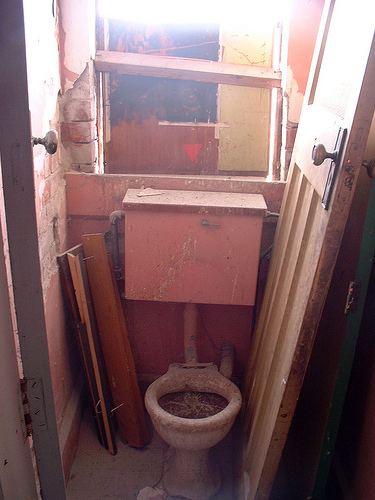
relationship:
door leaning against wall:
[214, 10, 345, 478] [274, 37, 363, 497]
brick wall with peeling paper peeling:
[24, 9, 81, 498] [24, 11, 171, 138]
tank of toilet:
[125, 189, 259, 302] [146, 366, 234, 497]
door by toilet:
[231, 0, 374, 477] [144, 361, 241, 498]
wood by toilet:
[52, 227, 152, 455] [146, 366, 234, 497]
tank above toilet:
[97, 190, 286, 305] [127, 339, 267, 475]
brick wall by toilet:
[24, 9, 81, 498] [144, 361, 241, 498]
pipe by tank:
[106, 203, 127, 286] [94, 173, 272, 317]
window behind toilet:
[93, 10, 278, 187] [146, 358, 257, 494]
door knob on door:
[310, 141, 338, 165] [231, 0, 374, 477]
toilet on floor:
[137, 356, 248, 499] [85, 439, 136, 498]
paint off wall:
[67, 166, 114, 217] [19, 7, 99, 261]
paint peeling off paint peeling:
[38, 158, 63, 303] [61, 63, 100, 172]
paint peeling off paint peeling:
[38, 158, 63, 303] [102, 173, 144, 189]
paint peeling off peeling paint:
[38, 158, 63, 303] [286, 3, 302, 165]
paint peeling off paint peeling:
[38, 158, 63, 303] [203, 181, 264, 192]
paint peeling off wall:
[38, 158, 63, 303] [31, 23, 108, 174]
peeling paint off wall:
[24, 0, 95, 413] [22, 0, 373, 491]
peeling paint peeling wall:
[24, 0, 95, 413] [285, 29, 325, 68]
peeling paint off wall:
[24, 0, 95, 413] [23, 0, 91, 128]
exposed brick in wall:
[35, 58, 105, 295] [16, 9, 95, 339]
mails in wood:
[91, 398, 123, 419] [68, 242, 127, 438]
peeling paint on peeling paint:
[24, 0, 95, 413] [286, 3, 302, 165]